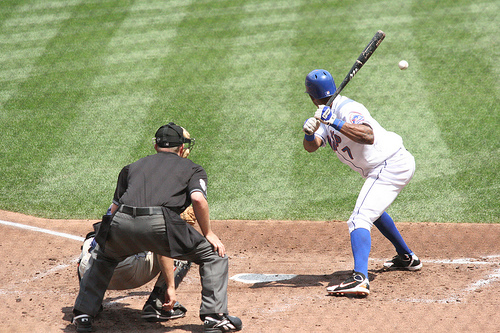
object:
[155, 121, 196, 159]
mask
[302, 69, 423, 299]
hitter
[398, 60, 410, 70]
baseball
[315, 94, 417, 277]
baseball uniform